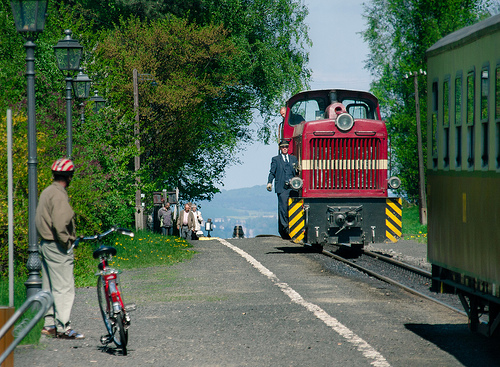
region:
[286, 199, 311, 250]
black and yellow warning sign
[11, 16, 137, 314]
Row of green light poles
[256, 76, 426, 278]
Red train on track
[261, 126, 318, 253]
Man stands on side of train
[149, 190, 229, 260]
People walking by the tracks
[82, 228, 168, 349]
The bike is red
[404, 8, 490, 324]
Brown and white car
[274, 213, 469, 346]
The tracks are embedded in the asphalt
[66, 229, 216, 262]
Yellow flowers next to the road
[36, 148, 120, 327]
The person is wearing a striped helmet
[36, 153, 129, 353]
The person is holding a bike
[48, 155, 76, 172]
red and white stripes helmet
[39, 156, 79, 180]
red and white stripes helmet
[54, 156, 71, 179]
red and white stripes helmet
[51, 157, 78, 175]
Red and White safety helmet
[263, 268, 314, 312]
Long white safety line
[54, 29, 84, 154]
Tall metal light post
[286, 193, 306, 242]
Caution sign on train engine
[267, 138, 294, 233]
Train Conductor hanging on train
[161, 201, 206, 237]
Group of people walking in distance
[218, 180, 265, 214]
Dark mountain range in distance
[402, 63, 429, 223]
Large grey light pole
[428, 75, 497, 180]
Group of windows on train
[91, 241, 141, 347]
Red bicycle parked on pavement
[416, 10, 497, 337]
a green train car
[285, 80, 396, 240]
a red and black train engine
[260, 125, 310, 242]
man standing and riding outside train engine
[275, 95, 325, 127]
man's head emerging from behind window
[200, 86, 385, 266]
ground descends behind engine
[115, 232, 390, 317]
yellow flowers dotting grass near tracks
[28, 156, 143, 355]
man standing beside a bicycle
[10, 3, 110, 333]
row of street lamps on posts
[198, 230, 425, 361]
white line on pavement near tracks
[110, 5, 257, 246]
people standing in a small group near trees